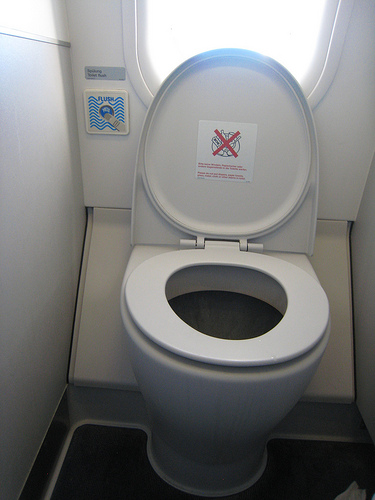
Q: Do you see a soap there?
A: No, there are no soaps.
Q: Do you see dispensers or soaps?
A: No, there are no soaps or dispensers.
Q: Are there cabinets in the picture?
A: No, there are no cabinets.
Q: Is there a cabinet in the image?
A: No, there are no cabinets.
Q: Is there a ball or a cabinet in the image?
A: No, there are no cabinets or balls.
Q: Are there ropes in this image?
A: No, there are no ropes.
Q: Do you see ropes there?
A: No, there are no ropes.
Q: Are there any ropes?
A: No, there are no ropes.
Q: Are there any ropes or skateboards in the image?
A: No, there are no ropes or skateboards.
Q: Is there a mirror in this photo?
A: No, there are no mirrors.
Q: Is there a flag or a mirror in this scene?
A: No, there are no mirrors or flags.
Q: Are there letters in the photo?
A: Yes, there are letters.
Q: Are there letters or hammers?
A: Yes, there are letters.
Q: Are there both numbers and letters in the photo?
A: No, there are letters but no numbers.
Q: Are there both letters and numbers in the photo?
A: No, there are letters but no numbers.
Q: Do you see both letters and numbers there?
A: No, there are letters but no numbers.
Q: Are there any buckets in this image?
A: No, there are no buckets.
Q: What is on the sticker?
A: The letters are on the sticker.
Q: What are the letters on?
A: The letters are on the sticker.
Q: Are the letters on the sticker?
A: Yes, the letters are on the sticker.